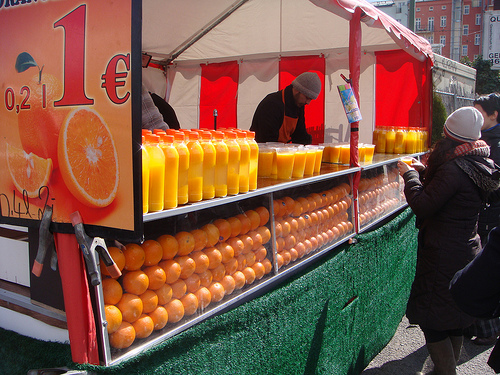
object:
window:
[440, 16, 447, 27]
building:
[412, 1, 500, 70]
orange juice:
[153, 128, 260, 210]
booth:
[0, 2, 475, 375]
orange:
[120, 243, 146, 271]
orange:
[154, 233, 179, 260]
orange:
[170, 231, 196, 257]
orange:
[211, 218, 231, 243]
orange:
[101, 304, 123, 334]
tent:
[198, 0, 457, 93]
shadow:
[345, 332, 500, 374]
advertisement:
[0, 0, 143, 245]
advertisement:
[0, 0, 143, 241]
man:
[249, 72, 323, 144]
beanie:
[291, 71, 322, 100]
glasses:
[275, 148, 297, 179]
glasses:
[291, 147, 310, 178]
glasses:
[302, 146, 319, 175]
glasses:
[362, 144, 376, 164]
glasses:
[319, 141, 376, 166]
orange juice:
[275, 146, 319, 179]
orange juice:
[372, 125, 428, 154]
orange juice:
[318, 142, 375, 166]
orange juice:
[134, 132, 205, 214]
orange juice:
[202, 142, 257, 198]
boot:
[418, 313, 455, 375]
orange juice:
[129, 125, 428, 212]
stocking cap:
[443, 106, 484, 143]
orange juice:
[244, 131, 259, 190]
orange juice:
[223, 132, 241, 195]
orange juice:
[170, 133, 190, 204]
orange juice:
[275, 147, 297, 179]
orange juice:
[328, 145, 341, 165]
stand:
[334, 83, 363, 167]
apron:
[275, 89, 302, 142]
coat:
[401, 139, 500, 345]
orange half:
[57, 105, 120, 209]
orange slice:
[4, 142, 54, 198]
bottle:
[144, 135, 166, 211]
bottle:
[185, 133, 204, 201]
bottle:
[209, 129, 228, 197]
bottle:
[237, 132, 251, 192]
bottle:
[246, 131, 259, 190]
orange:
[188, 229, 209, 251]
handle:
[213, 108, 219, 130]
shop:
[1, 0, 476, 375]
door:
[0, 38, 145, 356]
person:
[397, 105, 500, 375]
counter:
[141, 127, 375, 215]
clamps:
[30, 207, 123, 367]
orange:
[122, 255, 213, 304]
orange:
[330, 143, 341, 163]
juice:
[169, 132, 190, 204]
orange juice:
[137, 124, 258, 211]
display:
[84, 192, 276, 361]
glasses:
[254, 142, 325, 180]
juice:
[253, 141, 325, 179]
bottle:
[141, 127, 258, 214]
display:
[141, 128, 323, 216]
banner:
[2, 0, 143, 240]